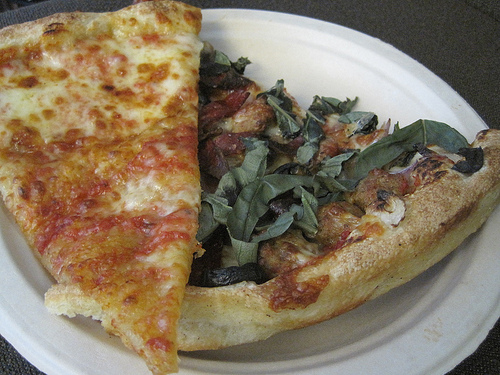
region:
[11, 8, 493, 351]
Pizza on the plate.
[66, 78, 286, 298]
Cheese and sauce on the pizza.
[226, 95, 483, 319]
Green herbs on the pizza.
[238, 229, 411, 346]
Crust on the pizza.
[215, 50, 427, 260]
Bacon on the pizza.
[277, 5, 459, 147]
White plate on the table.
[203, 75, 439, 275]
Vegetables on the pizza.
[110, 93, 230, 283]
Cheese on the pizza.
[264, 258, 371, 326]
Dark spot on the crust.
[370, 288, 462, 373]
Part of the plate.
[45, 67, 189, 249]
This is a slice of pizza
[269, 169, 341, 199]
This is sliced basil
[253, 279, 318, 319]
This is the crust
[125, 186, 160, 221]
This is melted cheese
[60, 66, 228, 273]
The cheese is brown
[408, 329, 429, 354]
The plate is paper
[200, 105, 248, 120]
This is red bacon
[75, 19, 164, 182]
This is a slice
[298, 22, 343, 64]
The plate is white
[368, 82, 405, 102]
This is a plate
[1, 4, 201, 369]
slice of cheese pizza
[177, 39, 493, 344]
slice of sausage pizza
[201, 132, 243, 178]
piece of sausage pizza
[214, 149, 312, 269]
basil leaves on pizza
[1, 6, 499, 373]
two slices of pizza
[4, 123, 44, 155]
cheese bubble on pizza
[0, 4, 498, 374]
pizza on paper plate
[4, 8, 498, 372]
white paper dinner plate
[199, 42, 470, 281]
green herbs on pizza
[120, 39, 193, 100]
melted cheese on pizza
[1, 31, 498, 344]
Two slices of pizza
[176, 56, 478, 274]
vegetables on a pizza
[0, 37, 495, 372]
a circular shaped plate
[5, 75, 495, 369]
pizza slices on a white plate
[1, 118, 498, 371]
a white plate under pizza slices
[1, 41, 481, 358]
the cheese pizza is on top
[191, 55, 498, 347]
a pizza slice with green and red toppings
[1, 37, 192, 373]
red sauce on the pizza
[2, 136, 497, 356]
the crust of a pizza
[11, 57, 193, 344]
melted cheese on a pizza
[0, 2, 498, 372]
two slices of pizza on white plate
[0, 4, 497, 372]
twi slices of pizza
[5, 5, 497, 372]
round white plate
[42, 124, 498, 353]
pizza edge crust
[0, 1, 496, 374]
white ceramic plate with lip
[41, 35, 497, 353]
slice of pizza with meat and greens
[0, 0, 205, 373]
pizza with browned melted cheese topping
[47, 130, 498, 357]
thick pizza crust edge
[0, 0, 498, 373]
white plate with flat edge